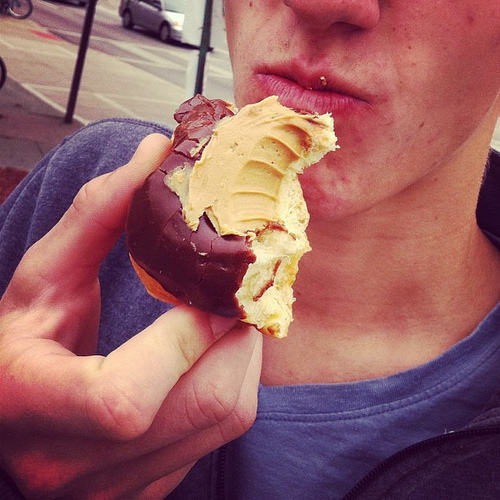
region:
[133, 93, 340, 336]
donut being eaten by a teen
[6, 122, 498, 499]
purple t shirt being worn by teen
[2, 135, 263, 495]
right hand holding a half eaten donut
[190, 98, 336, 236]
peanut butter on a donut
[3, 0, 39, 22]
the front tire of a bike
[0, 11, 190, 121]
city sidewalk in background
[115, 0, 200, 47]
grey sedan driving on street in background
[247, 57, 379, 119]
closed red lips on face of teen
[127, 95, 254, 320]
chocolate icing on half eaten donut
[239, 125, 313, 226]
bite marks in peanut butter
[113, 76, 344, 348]
Piece of donut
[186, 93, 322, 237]
Peanut butter on a donut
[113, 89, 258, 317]
Donut is cover with chocolate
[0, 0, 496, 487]
Person holds a donut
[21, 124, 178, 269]
Thumb holding a donut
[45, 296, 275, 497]
Four fingers holding a donut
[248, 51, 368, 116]
Mouth is closed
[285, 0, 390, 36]
Nose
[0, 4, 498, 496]
Person wearing a purple shirt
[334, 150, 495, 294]
Neck of a person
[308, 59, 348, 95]
small white spot on lips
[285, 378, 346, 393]
edge of blue tee shirt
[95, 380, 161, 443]
lines in knuckles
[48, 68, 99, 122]
brown feet of chair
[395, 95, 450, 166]
small pimples on face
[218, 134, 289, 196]
lines in peanut butter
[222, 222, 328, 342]
half eaten edge of pastry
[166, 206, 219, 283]
brown chocolate on pastry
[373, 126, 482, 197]
defined chin on person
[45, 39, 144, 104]
white lines on the floor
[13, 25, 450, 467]
fingers and thumb holding doughnut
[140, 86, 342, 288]
chocolate frosted doughnut with peanut butter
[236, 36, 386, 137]
lips closed near doughnut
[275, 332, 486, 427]
seam along edge of neckline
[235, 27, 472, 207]
blemishes around mouth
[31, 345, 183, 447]
bent pointer finger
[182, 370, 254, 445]
wrinkles across fingers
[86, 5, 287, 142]
silver car behind eater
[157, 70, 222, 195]
cracks in chocolate frosting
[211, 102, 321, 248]
repeated grooves on filling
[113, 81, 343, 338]
partially eaten pastry in hand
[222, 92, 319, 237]
peanut butter with teeth marks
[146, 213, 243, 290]
chocolate frosting on pastry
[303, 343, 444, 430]
collar on blue tee shirt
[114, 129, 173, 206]
thumb on side of pastry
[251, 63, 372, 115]
crumb on closed lips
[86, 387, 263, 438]
three knuckles on hand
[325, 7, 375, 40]
nostril on man's nose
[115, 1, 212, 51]
car driving on street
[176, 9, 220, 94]
signs on pole in sidewalk